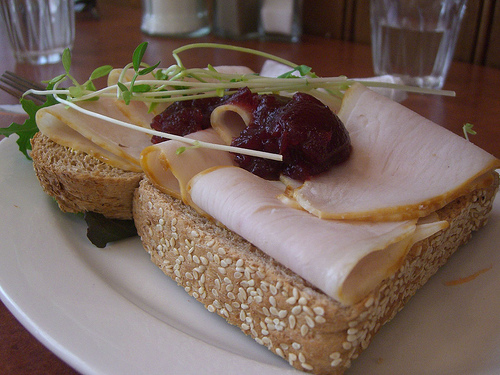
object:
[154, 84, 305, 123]
turkey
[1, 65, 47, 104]
fork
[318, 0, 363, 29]
ground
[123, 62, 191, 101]
sprouts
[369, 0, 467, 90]
container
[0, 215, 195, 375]
white wheels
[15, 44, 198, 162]
leaves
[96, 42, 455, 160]
stem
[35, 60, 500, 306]
lunch meat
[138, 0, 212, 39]
container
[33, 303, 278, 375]
white meat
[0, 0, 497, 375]
table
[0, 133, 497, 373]
plate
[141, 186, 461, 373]
seeds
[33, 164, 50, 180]
seeds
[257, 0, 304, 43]
container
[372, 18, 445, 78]
water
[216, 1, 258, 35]
pepper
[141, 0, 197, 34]
salt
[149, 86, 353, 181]
sauce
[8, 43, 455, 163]
garnish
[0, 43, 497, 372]
food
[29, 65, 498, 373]
bread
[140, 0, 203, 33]
sugar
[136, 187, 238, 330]
sesame seeds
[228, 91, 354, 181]
berry preserves